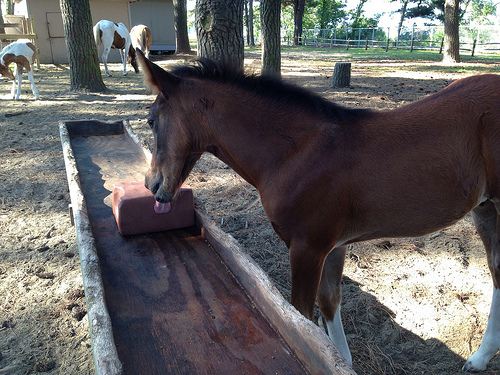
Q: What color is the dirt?
A: Brown.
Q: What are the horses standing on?
A: Dirt.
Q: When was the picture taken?
A: Daytime.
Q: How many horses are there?
A: Four.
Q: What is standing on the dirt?
A: The horses.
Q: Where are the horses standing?
A: On the dirt.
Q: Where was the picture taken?
A: At a ranch.